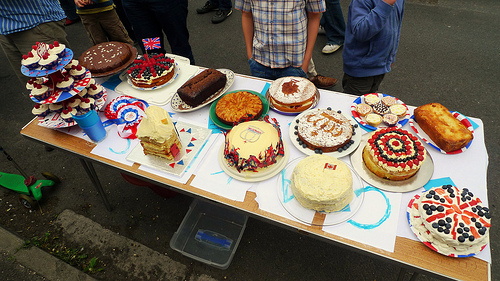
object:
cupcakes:
[389, 104, 407, 117]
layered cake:
[135, 106, 183, 161]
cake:
[218, 112, 291, 182]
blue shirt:
[342, 0, 405, 77]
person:
[343, 27, 403, 97]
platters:
[37, 83, 108, 129]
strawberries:
[413, 158, 420, 166]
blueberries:
[437, 206, 445, 212]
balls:
[444, 229, 451, 234]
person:
[341, 0, 405, 96]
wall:
[226, 85, 280, 136]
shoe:
[322, 44, 344, 53]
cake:
[406, 184, 492, 260]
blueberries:
[425, 208, 433, 215]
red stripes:
[426, 213, 446, 223]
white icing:
[437, 237, 455, 252]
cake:
[294, 107, 359, 155]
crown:
[306, 112, 343, 138]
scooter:
[0, 146, 62, 210]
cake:
[127, 53, 181, 91]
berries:
[152, 73, 158, 77]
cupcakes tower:
[20, 41, 107, 129]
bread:
[414, 102, 473, 153]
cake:
[77, 42, 139, 79]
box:
[168, 198, 250, 270]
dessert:
[177, 68, 228, 107]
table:
[19, 54, 493, 281]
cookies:
[364, 114, 383, 127]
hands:
[299, 62, 313, 74]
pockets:
[282, 67, 308, 80]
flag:
[142, 37, 162, 51]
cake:
[291, 154, 355, 214]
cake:
[362, 128, 427, 187]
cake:
[266, 76, 321, 115]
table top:
[19, 55, 492, 281]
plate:
[170, 68, 236, 113]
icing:
[38, 56, 59, 66]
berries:
[42, 51, 50, 60]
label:
[196, 231, 231, 247]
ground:
[3, 0, 500, 278]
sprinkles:
[273, 101, 288, 108]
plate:
[277, 156, 366, 227]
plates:
[408, 110, 475, 155]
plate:
[350, 93, 410, 131]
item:
[70, 109, 107, 142]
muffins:
[56, 76, 75, 92]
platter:
[20, 47, 74, 77]